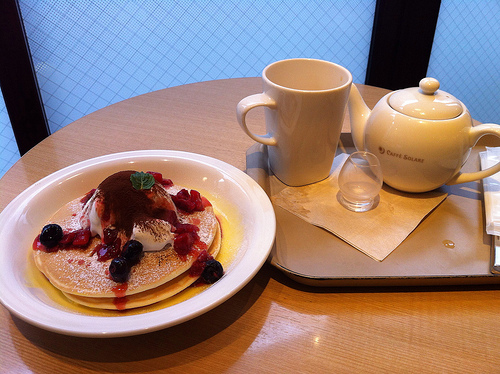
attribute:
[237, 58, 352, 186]
cup — white, plain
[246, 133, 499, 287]
tray — light brown, tan colored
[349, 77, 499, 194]
teapot — white, round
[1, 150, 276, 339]
bowl — white, small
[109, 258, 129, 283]
fruit — served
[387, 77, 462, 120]
top — white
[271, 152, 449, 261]
napkin — white, lying down, square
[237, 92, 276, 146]
handle — white, ceramic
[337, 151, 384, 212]
glass — empty, small, clear, round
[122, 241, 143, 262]
fruit — served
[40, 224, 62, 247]
fruit — served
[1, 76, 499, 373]
table — small, light colored, round, wood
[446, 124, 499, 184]
handle — ceramic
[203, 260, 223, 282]
fruit — served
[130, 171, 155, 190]
mint leaf — green